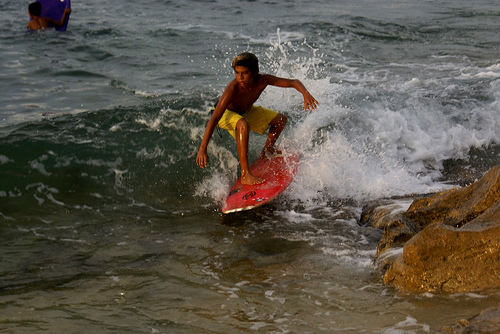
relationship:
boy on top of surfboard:
[192, 51, 325, 188] [219, 148, 297, 220]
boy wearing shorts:
[192, 51, 325, 188] [208, 103, 288, 136]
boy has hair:
[192, 51, 325, 188] [229, 51, 263, 74]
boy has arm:
[192, 51, 325, 188] [195, 79, 236, 150]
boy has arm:
[192, 51, 325, 188] [269, 69, 315, 91]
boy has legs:
[192, 51, 325, 188] [222, 108, 290, 169]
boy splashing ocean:
[192, 51, 325, 188] [0, 0, 499, 333]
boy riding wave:
[192, 51, 325, 188] [4, 92, 499, 180]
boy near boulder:
[192, 51, 325, 188] [358, 154, 499, 305]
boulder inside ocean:
[358, 154, 499, 305] [3, 2, 497, 326]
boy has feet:
[192, 51, 325, 188] [238, 149, 288, 187]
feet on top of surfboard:
[238, 149, 288, 187] [219, 148, 297, 220]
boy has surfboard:
[192, 51, 325, 188] [219, 148, 297, 220]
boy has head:
[192, 51, 325, 188] [229, 51, 263, 90]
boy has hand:
[192, 51, 325, 188] [189, 148, 213, 170]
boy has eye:
[192, 51, 325, 188] [242, 69, 255, 77]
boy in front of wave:
[192, 51, 325, 188] [4, 92, 499, 180]